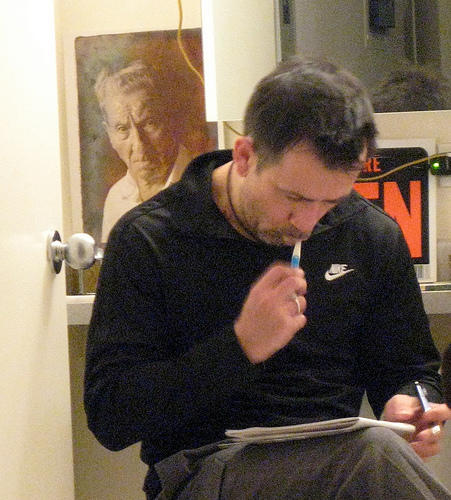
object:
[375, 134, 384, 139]
ground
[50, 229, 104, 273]
door handle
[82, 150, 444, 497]
black shirt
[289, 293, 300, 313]
ring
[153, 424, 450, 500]
grey pants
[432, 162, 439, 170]
light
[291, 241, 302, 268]
toothbrush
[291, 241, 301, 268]
pen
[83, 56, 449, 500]
guy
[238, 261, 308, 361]
hand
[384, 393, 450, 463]
hand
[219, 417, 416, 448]
paper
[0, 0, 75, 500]
door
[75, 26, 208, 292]
poster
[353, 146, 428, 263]
sign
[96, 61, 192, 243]
man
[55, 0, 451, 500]
wall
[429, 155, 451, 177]
box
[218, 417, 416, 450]
lap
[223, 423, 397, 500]
pad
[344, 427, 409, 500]
knee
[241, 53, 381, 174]
hair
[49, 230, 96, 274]
silver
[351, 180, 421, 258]
"open"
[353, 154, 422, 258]
lettering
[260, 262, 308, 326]
finger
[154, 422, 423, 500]
pair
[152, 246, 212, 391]
color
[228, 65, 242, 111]
color